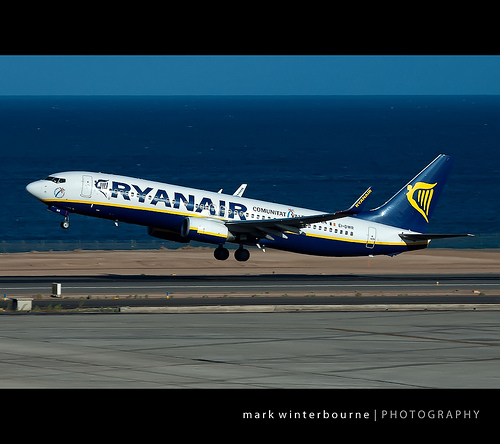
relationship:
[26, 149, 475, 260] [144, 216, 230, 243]
jet has engines